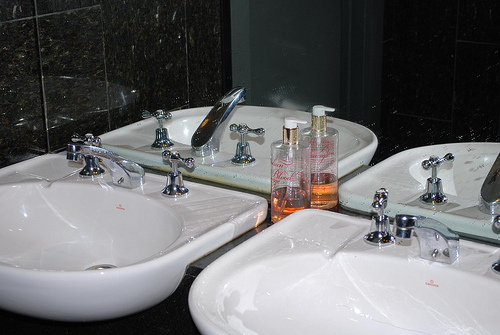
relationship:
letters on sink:
[113, 202, 129, 215] [2, 151, 265, 323]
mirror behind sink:
[32, 2, 500, 252] [2, 151, 265, 323]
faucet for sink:
[82, 144, 143, 186] [2, 151, 265, 323]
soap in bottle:
[275, 187, 309, 214] [271, 116, 308, 221]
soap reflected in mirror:
[275, 187, 309, 214] [32, 2, 500, 252]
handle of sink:
[159, 148, 194, 200] [2, 151, 265, 323]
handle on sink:
[69, 130, 104, 178] [2, 151, 265, 323]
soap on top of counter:
[275, 187, 309, 214] [3, 147, 381, 334]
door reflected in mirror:
[229, 1, 386, 146] [32, 2, 500, 252]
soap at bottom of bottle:
[275, 187, 309, 214] [271, 116, 308, 221]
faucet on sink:
[82, 144, 143, 186] [2, 151, 265, 323]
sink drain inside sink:
[86, 263, 115, 277] [2, 151, 265, 323]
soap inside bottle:
[275, 187, 309, 214] [271, 116, 308, 221]